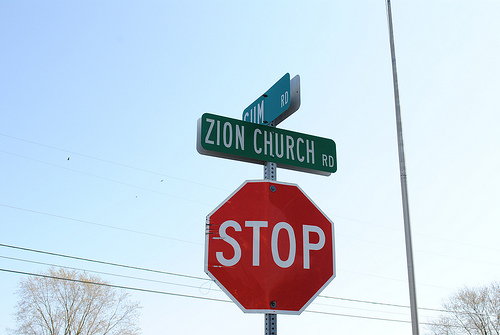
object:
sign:
[197, 112, 338, 177]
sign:
[202, 179, 337, 315]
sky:
[0, 0, 499, 334]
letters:
[215, 120, 222, 146]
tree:
[7, 264, 144, 334]